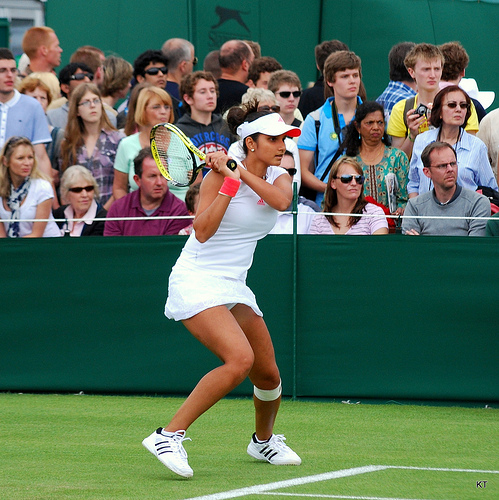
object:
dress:
[163, 159, 291, 323]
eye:
[268, 136, 277, 141]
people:
[0, 25, 499, 239]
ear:
[245, 136, 255, 151]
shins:
[164, 363, 239, 436]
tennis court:
[0, 392, 499, 500]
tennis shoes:
[247, 431, 302, 467]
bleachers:
[2, 233, 497, 402]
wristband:
[218, 175, 240, 198]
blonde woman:
[111, 86, 204, 203]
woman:
[52, 165, 107, 238]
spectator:
[0, 25, 499, 240]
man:
[384, 42, 480, 160]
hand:
[205, 152, 230, 169]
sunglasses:
[333, 174, 366, 184]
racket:
[149, 122, 237, 187]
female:
[141, 98, 302, 479]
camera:
[413, 103, 428, 120]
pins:
[141, 425, 195, 480]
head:
[226, 98, 287, 165]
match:
[0, 100, 499, 500]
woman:
[308, 157, 389, 234]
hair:
[60, 164, 101, 206]